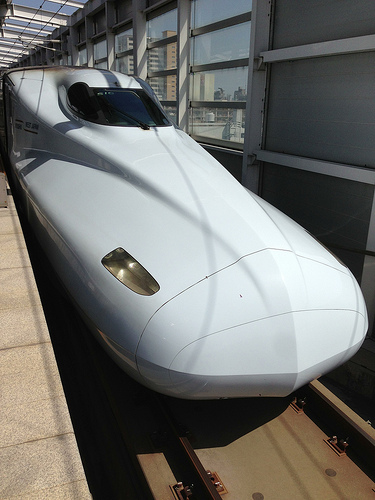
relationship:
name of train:
[12, 117, 43, 136] [11, 66, 360, 343]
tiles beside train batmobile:
[3, 172, 88, 498] [2, 65, 369, 400]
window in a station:
[144, 13, 187, 105] [0, 10, 375, 499]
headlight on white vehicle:
[100, 246, 160, 296] [2, 27, 365, 331]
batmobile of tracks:
[2, 65, 369, 400] [85, 337, 373, 498]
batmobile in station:
[2, 65, 369, 400] [2, 1, 373, 496]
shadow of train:
[14, 202, 294, 452] [36, 67, 284, 279]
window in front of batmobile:
[65, 81, 172, 130] [2, 65, 369, 400]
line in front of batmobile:
[167, 306, 370, 370] [2, 65, 369, 400]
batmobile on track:
[2, 65, 369, 400] [6, 217, 353, 498]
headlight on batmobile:
[100, 246, 160, 296] [2, 65, 369, 400]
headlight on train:
[92, 246, 167, 300] [0, 56, 362, 317]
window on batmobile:
[65, 81, 172, 130] [3, 54, 335, 417]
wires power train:
[23, 9, 60, 48] [8, 29, 372, 401]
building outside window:
[120, 27, 185, 110] [182, 12, 251, 152]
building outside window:
[190, 65, 219, 118] [144, 15, 180, 113]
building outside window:
[120, 27, 185, 110] [90, 38, 107, 65]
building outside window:
[190, 65, 219, 118] [73, 50, 87, 64]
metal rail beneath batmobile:
[162, 405, 220, 499] [2, 65, 369, 400]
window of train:
[65, 81, 172, 130] [28, 60, 263, 235]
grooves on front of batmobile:
[138, 246, 362, 378] [2, 65, 369, 400]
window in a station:
[114, 23, 135, 74] [2, 1, 373, 496]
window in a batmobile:
[186, 17, 254, 66] [2, 65, 369, 400]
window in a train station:
[186, 17, 254, 66] [4, 4, 364, 498]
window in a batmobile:
[144, 13, 170, 33] [2, 65, 369, 400]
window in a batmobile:
[89, 42, 107, 67] [2, 65, 369, 400]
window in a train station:
[197, 46, 289, 150] [23, 29, 365, 443]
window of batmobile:
[64, 66, 169, 153] [2, 65, 369, 400]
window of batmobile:
[191, 2, 245, 141] [2, 65, 369, 400]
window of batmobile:
[145, 11, 177, 113] [2, 65, 369, 400]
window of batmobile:
[113, 30, 134, 72] [2, 65, 369, 400]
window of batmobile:
[89, 42, 107, 67] [2, 65, 369, 400]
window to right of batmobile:
[65, 81, 172, 130] [2, 65, 369, 400]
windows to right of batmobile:
[191, 2, 244, 144] [2, 65, 369, 400]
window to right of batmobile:
[114, 28, 133, 54] [2, 65, 369, 400]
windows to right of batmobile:
[75, 45, 87, 66] [2, 65, 369, 400]